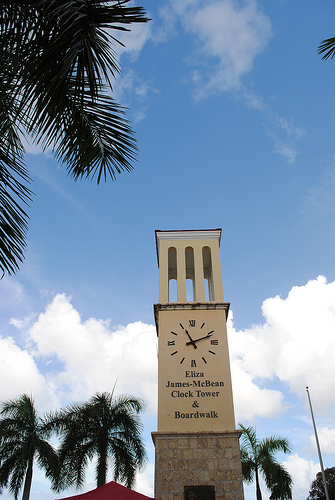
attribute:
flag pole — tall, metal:
[305, 385, 329, 497]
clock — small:
[165, 318, 219, 367]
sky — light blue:
[0, 2, 333, 497]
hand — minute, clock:
[193, 334, 216, 346]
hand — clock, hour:
[181, 325, 200, 349]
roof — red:
[59, 476, 119, 497]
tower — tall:
[149, 225, 244, 494]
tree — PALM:
[44, 391, 147, 490]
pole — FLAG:
[303, 384, 324, 488]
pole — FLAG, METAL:
[304, 384, 323, 487]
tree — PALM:
[51, 391, 144, 489]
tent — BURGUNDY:
[71, 478, 150, 495]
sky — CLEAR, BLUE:
[46, 144, 301, 281]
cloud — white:
[24, 291, 158, 414]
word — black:
[173, 409, 219, 418]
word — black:
[170, 389, 193, 397]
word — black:
[194, 388, 220, 397]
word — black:
[164, 379, 224, 386]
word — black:
[184, 369, 204, 376]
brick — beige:
[157, 437, 167, 448]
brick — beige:
[176, 437, 188, 444]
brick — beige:
[212, 467, 228, 479]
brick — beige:
[223, 445, 233, 459]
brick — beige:
[154, 480, 174, 492]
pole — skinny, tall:
[304, 384, 324, 497]